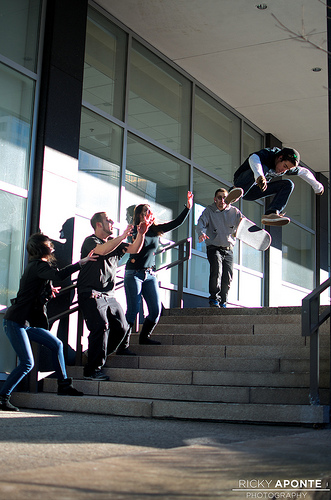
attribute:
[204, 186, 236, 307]
man — skateboarding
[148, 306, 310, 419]
staircase — concrete, cement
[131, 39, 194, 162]
window — glass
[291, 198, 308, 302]
door — glass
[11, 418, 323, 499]
sidewalk — paved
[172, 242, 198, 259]
rail — metal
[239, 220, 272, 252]
skateboard — black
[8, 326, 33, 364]
jeans — blue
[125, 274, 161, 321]
jeans — blue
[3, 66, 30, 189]
window — glass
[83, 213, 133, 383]
man — reaching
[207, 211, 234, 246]
sweatshirt — gray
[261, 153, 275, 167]
t-shirt — black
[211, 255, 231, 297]
pants — black